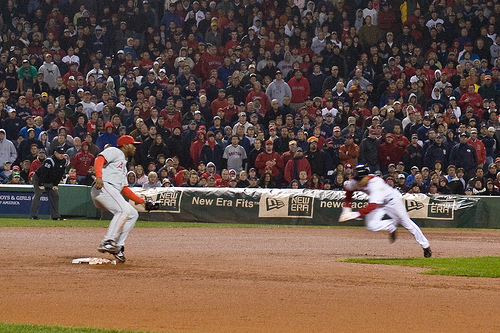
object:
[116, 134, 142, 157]
man's head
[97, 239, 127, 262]
foot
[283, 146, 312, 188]
person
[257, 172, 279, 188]
person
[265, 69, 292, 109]
person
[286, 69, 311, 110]
person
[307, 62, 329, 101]
person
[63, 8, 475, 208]
stands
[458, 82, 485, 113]
person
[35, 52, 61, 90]
person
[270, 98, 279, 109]
ball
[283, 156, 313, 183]
red jackets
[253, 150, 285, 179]
sweatshirts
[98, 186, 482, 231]
advertising banner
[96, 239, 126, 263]
cleats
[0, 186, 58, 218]
advertising banner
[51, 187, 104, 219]
wall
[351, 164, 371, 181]
helmet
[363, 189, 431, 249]
pants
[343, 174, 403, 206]
white jersey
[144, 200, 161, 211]
glove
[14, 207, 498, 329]
baseball field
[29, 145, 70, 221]
dark clothing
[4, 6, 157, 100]
spectators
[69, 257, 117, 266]
base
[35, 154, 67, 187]
jacket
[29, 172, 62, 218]
pants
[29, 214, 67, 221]
shoes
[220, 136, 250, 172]
person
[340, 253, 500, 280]
grass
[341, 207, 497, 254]
infield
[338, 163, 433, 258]
baseball player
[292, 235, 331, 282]
base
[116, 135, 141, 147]
cap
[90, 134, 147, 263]
baseball infielder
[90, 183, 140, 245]
pants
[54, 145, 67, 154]
hat